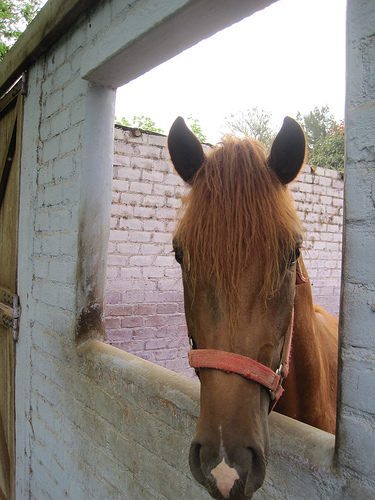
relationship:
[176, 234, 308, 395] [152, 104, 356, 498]
bride of horse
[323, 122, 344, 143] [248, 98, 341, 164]
flowers on bushes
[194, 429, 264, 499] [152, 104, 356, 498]
nose of horse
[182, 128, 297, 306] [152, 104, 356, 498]
hair of horse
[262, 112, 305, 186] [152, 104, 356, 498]
left ear of horse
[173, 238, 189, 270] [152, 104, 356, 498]
right eye of horse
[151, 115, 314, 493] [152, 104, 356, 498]
head of horse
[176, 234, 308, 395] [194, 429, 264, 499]
bride on nose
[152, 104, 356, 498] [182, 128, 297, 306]
horse has hair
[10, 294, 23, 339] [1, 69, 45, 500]
hinge of door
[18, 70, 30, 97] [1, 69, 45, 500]
hinge of door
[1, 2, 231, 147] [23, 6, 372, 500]
trees over wall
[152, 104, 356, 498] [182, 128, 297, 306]
horse with hair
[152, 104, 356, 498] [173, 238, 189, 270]
horse has right eye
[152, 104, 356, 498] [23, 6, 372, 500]
horse surrounded by wall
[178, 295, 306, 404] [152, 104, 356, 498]
bridle on horse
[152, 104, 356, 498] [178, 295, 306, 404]
horse with bridle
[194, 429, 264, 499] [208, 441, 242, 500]
nose with spot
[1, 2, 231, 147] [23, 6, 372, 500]
trees sticking up over wall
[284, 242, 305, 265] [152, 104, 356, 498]
left eye of horse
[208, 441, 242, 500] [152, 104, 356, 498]
spot on horse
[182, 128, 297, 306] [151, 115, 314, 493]
hair on head